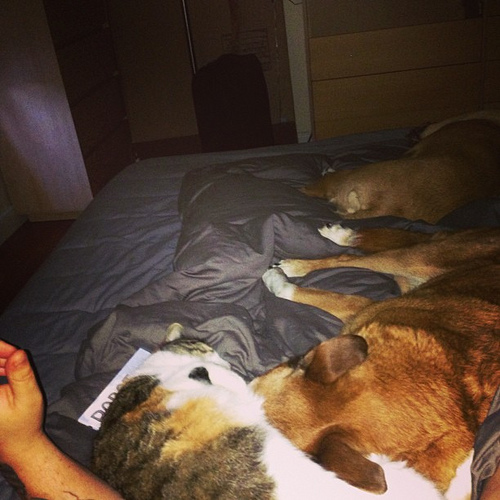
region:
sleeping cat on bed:
[90, 320, 434, 499]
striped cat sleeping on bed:
[87, 318, 448, 498]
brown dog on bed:
[244, 221, 499, 496]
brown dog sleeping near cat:
[239, 220, 498, 499]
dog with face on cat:
[229, 220, 496, 498]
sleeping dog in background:
[292, 115, 499, 227]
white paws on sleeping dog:
[257, 218, 359, 309]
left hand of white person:
[0, 333, 133, 498]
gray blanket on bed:
[37, 145, 414, 499]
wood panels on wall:
[305, 13, 497, 143]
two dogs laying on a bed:
[283, 108, 496, 485]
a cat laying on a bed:
[98, 343, 304, 499]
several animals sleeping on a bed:
[109, 109, 478, 499]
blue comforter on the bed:
[117, 189, 172, 283]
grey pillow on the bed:
[170, 148, 315, 273]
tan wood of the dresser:
[20, 75, 60, 182]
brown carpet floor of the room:
[6, 220, 61, 276]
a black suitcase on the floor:
[185, 50, 280, 136]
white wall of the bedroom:
[140, 33, 189, 116]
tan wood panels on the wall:
[328, 40, 475, 114]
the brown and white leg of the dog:
[260, 262, 370, 324]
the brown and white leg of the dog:
[277, 243, 473, 286]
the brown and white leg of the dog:
[322, 220, 449, 260]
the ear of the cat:
[166, 318, 181, 340]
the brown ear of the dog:
[305, 331, 365, 383]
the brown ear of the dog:
[317, 430, 388, 490]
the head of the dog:
[252, 362, 387, 455]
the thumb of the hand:
[5, 350, 38, 405]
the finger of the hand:
[1, 338, 13, 356]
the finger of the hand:
[0, 357, 8, 369]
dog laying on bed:
[289, 107, 499, 229]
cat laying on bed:
[85, 324, 350, 496]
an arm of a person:
[2, 324, 87, 497]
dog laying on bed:
[240, 266, 497, 476]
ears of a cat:
[168, 322, 227, 345]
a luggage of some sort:
[183, 47, 283, 149]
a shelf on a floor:
[15, 0, 145, 217]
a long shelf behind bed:
[299, 19, 499, 131]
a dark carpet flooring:
[15, 230, 51, 256]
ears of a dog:
[297, 334, 392, 499]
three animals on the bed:
[57, 81, 497, 498]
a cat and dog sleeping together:
[89, 268, 496, 488]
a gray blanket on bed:
[85, 162, 436, 388]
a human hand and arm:
[1, 330, 111, 499]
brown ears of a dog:
[290, 332, 428, 493]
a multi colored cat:
[99, 314, 340, 499]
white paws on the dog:
[244, 232, 374, 327]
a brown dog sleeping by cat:
[273, 207, 495, 484]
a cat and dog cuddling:
[80, 284, 472, 498]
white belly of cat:
[185, 357, 320, 499]